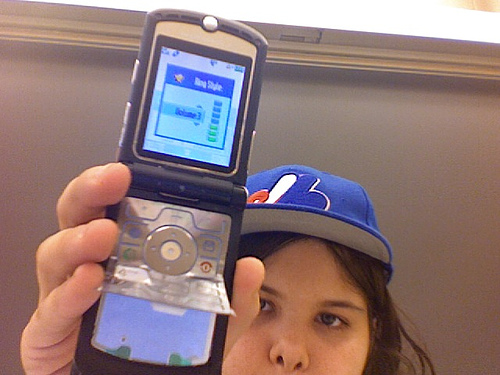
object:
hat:
[241, 163, 392, 285]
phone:
[72, 7, 275, 374]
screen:
[142, 34, 257, 175]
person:
[19, 164, 437, 373]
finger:
[57, 160, 132, 231]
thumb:
[224, 256, 267, 359]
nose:
[268, 314, 310, 373]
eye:
[314, 309, 351, 330]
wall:
[3, 39, 499, 375]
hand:
[19, 163, 268, 375]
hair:
[238, 231, 436, 373]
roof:
[1, 0, 500, 90]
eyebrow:
[320, 299, 368, 313]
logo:
[246, 170, 332, 213]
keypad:
[97, 192, 234, 316]